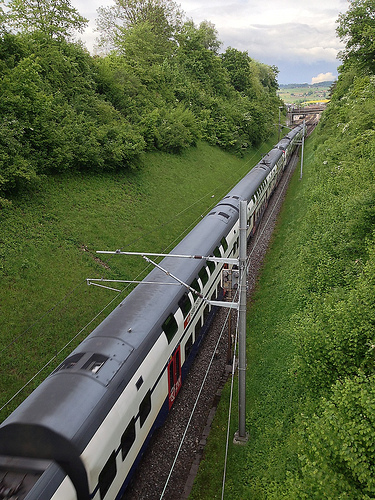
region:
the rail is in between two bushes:
[173, 117, 351, 399]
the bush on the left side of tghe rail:
[297, 220, 369, 353]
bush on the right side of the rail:
[39, 88, 127, 197]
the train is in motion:
[77, 231, 277, 485]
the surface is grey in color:
[129, 202, 240, 287]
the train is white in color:
[91, 261, 245, 472]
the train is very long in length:
[111, 158, 286, 425]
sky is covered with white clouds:
[257, 26, 308, 43]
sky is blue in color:
[286, 57, 305, 77]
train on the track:
[75, 230, 175, 495]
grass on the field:
[5, 203, 83, 292]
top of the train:
[72, 312, 121, 378]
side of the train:
[182, 276, 247, 357]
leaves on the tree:
[276, 343, 369, 468]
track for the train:
[159, 410, 208, 475]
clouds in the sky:
[274, 13, 329, 59]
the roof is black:
[32, 398, 64, 426]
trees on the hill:
[25, 103, 135, 173]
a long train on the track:
[2, 122, 307, 499]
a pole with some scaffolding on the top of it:
[86, 230, 252, 452]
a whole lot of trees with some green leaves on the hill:
[3, 1, 286, 169]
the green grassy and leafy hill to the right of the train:
[209, 36, 374, 498]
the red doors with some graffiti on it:
[167, 342, 182, 405]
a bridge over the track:
[284, 104, 325, 120]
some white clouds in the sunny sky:
[205, 3, 340, 83]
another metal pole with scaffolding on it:
[277, 118, 308, 178]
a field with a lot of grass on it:
[277, 80, 327, 104]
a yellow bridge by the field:
[305, 97, 327, 104]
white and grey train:
[61, 134, 289, 491]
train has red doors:
[158, 355, 188, 400]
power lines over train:
[123, 119, 281, 372]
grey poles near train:
[223, 181, 244, 459]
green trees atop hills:
[1, 66, 233, 160]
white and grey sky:
[264, 16, 314, 70]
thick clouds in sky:
[255, 6, 313, 70]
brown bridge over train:
[281, 93, 334, 132]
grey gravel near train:
[150, 356, 221, 497]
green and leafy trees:
[293, 285, 374, 484]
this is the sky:
[253, 9, 325, 65]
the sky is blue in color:
[285, 65, 305, 79]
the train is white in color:
[134, 363, 162, 403]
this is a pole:
[221, 199, 252, 385]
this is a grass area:
[20, 240, 48, 299]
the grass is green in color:
[21, 231, 42, 251]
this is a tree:
[310, 227, 373, 344]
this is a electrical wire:
[213, 311, 237, 347]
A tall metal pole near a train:
[236, 199, 246, 442]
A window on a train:
[136, 386, 152, 425]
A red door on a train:
[162, 345, 182, 407]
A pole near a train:
[301, 113, 305, 170]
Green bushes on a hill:
[2, 28, 140, 190]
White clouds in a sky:
[1, 1, 352, 66]